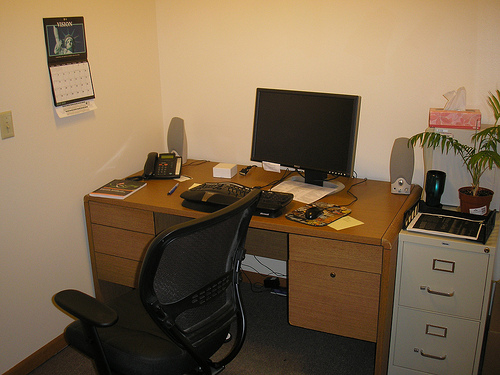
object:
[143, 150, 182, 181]
phone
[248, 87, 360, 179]
monitor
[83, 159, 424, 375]
desk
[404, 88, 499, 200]
plant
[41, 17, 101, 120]
calendar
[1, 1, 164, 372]
wall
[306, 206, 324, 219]
mouse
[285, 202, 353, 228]
mousepad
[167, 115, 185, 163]
speaker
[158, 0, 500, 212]
wall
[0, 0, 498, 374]
office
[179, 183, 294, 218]
keyboard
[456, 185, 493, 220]
brown pot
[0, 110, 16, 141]
switch plate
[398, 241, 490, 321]
file cabinet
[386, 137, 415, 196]
speaker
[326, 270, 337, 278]
lock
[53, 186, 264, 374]
black chair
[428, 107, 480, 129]
box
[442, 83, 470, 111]
tissues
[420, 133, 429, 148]
leaves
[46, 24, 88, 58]
picture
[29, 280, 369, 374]
carpeting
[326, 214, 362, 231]
paper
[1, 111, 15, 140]
light switch